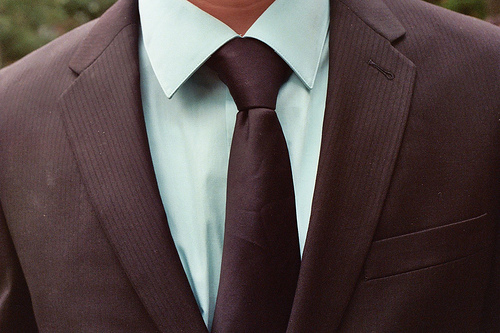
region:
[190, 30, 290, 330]
the tie is brown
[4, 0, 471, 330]
the coat is brown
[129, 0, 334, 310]
THIS IS WHITE SHIRT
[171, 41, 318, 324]
this is a tie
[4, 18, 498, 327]
this is a coat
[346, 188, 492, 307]
this is a breast pocket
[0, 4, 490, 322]
this is a man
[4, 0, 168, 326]
the coat has tiny stripes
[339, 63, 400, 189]
the coat has tiny stripes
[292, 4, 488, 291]
the coat has tiny stripes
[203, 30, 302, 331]
A black tie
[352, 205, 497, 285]
The left pocket of the suit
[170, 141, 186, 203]
Part of the blue shirt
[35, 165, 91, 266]
Part of the suit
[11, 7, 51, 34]
Part of the green tree in distance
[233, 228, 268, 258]
A wrinkle on the tie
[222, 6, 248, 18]
Part of the neck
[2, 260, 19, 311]
A wrinkle on the suit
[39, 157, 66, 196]
A white spot on the suit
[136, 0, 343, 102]
The collar of the shirt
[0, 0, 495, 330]
Person wearing a suit.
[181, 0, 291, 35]
Neck of the person.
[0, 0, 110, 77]
Green plants in the background.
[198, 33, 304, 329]
Navy tie on the person.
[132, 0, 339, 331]
Blue shirt on person.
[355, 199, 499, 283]
Pocket on suit jacket.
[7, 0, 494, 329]
Stripes on the suit jacket.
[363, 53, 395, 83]
button hole on lapel.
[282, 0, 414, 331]
Lapel on the jacket.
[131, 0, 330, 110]
collar on the shirt.